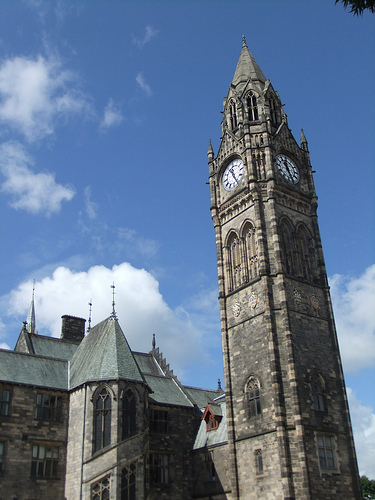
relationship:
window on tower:
[226, 224, 255, 264] [150, 8, 313, 317]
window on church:
[226, 224, 255, 264] [2, 272, 184, 477]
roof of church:
[37, 335, 187, 396] [2, 272, 184, 477]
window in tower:
[226, 224, 255, 264] [150, 8, 313, 317]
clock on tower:
[213, 134, 256, 201] [150, 8, 313, 317]